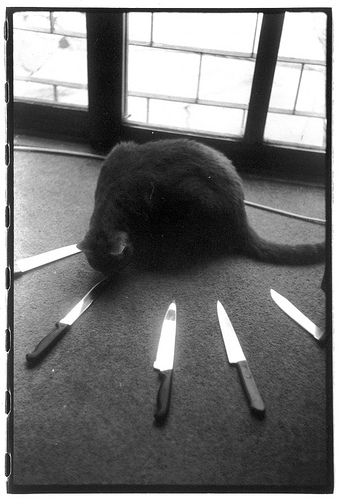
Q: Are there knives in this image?
A: Yes, there is a knife.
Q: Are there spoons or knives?
A: Yes, there is a knife.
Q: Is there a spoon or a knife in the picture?
A: Yes, there is a knife.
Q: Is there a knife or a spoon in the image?
A: Yes, there is a knife.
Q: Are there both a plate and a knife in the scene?
A: No, there is a knife but no plates.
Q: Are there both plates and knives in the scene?
A: No, there is a knife but no plates.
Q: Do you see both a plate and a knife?
A: No, there is a knife but no plates.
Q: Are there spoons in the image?
A: No, there are no spoons.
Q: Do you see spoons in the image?
A: No, there are no spoons.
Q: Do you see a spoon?
A: No, there are no spoons.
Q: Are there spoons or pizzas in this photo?
A: No, there are no spoons or pizzas.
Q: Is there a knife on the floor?
A: Yes, there is a knife on the floor.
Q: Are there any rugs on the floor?
A: No, there is a knife on the floor.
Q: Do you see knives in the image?
A: Yes, there is a knife.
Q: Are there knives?
A: Yes, there is a knife.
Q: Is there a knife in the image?
A: Yes, there is a knife.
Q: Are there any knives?
A: Yes, there is a knife.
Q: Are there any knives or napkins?
A: Yes, there is a knife.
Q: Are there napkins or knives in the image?
A: Yes, there is a knife.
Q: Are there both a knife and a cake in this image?
A: No, there is a knife but no cakes.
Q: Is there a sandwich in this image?
A: No, there are no sandwiches.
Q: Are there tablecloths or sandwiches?
A: No, there are no sandwiches or tablecloths.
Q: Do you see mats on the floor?
A: No, there is a knife on the floor.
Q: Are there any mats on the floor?
A: No, there is a knife on the floor.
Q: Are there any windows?
A: Yes, there is a window.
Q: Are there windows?
A: Yes, there is a window.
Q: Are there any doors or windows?
A: Yes, there is a window.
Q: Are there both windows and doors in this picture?
A: No, there is a window but no doors.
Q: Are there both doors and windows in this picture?
A: No, there is a window but no doors.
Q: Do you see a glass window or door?
A: Yes, there is a glass window.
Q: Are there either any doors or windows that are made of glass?
A: Yes, the window is made of glass.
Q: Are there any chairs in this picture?
A: No, there are no chairs.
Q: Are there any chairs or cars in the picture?
A: No, there are no chairs or cars.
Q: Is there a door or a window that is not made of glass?
A: No, there is a window but it is made of glass.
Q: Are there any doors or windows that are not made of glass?
A: No, there is a window but it is made of glass.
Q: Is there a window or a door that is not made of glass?
A: No, there is a window but it is made of glass.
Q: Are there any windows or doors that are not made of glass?
A: No, there is a window but it is made of glass.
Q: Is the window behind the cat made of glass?
A: Yes, the window is made of glass.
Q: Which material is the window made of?
A: The window is made of glass.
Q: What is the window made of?
A: The window is made of glass.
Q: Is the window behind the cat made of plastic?
A: No, the window is made of glass.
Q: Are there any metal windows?
A: No, there is a window but it is made of glass.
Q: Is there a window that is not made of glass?
A: No, there is a window but it is made of glass.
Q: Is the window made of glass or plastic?
A: The window is made of glass.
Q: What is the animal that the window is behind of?
A: The animal is a cat.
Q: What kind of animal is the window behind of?
A: The window is behind the cat.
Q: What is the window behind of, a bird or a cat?
A: The window is behind a cat.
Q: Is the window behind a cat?
A: Yes, the window is behind a cat.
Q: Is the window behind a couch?
A: No, the window is behind a cat.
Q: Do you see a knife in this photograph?
A: Yes, there is a knife.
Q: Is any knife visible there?
A: Yes, there is a knife.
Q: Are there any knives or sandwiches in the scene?
A: Yes, there is a knife.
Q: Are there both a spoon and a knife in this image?
A: No, there is a knife but no spoons.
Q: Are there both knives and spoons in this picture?
A: No, there is a knife but no spoons.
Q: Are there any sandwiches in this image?
A: No, there are no sandwiches.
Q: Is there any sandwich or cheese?
A: No, there are no sandwiches or cheese.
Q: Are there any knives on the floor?
A: Yes, there is a knife on the floor.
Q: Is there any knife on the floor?
A: Yes, there is a knife on the floor.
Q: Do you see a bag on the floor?
A: No, there is a knife on the floor.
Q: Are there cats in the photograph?
A: Yes, there is a cat.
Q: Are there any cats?
A: Yes, there is a cat.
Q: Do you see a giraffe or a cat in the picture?
A: Yes, there is a cat.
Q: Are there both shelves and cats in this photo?
A: No, there is a cat but no shelves.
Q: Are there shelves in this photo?
A: No, there are no shelves.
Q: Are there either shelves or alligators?
A: No, there are no shelves or alligators.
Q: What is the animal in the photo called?
A: The animal is a cat.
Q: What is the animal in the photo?
A: The animal is a cat.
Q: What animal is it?
A: The animal is a cat.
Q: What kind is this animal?
A: That is a cat.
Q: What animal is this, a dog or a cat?
A: That is a cat.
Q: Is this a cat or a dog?
A: This is a cat.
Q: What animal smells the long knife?
A: The cat smells the knife.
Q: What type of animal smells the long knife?
A: The animal is a cat.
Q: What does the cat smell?
A: The cat smells the knife.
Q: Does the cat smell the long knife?
A: Yes, the cat smells the knife.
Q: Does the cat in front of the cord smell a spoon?
A: No, the cat smells the knife.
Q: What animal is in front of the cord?
A: The cat is in front of the cord.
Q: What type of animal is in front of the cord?
A: The animal is a cat.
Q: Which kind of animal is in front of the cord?
A: The animal is a cat.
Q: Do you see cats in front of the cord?
A: Yes, there is a cat in front of the cord.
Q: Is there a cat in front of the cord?
A: Yes, there is a cat in front of the cord.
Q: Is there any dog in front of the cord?
A: No, there is a cat in front of the cord.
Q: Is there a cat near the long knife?
A: Yes, there is a cat near the knife.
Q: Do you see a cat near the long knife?
A: Yes, there is a cat near the knife.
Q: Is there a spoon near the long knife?
A: No, there is a cat near the knife.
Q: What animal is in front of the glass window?
A: The cat is in front of the window.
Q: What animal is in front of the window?
A: The cat is in front of the window.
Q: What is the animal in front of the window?
A: The animal is a cat.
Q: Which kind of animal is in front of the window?
A: The animal is a cat.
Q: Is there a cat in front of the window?
A: Yes, there is a cat in front of the window.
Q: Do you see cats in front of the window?
A: Yes, there is a cat in front of the window.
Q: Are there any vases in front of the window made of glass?
A: No, there is a cat in front of the window.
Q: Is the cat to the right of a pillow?
A: No, the cat is to the right of a knife.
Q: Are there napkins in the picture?
A: No, there are no napkins.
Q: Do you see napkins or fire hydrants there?
A: No, there are no napkins or fire hydrants.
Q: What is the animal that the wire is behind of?
A: The animal is a cat.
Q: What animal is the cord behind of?
A: The wire is behind the cat.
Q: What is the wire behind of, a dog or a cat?
A: The wire is behind a cat.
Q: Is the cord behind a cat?
A: Yes, the cord is behind a cat.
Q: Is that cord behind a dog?
A: No, the cord is behind a cat.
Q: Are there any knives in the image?
A: Yes, there is a knife.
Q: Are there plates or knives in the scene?
A: Yes, there is a knife.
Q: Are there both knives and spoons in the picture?
A: No, there is a knife but no spoons.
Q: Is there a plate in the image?
A: No, there are no plates.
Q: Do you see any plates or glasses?
A: No, there are no plates or glasses.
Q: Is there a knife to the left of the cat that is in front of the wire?
A: Yes, there is a knife to the left of the cat.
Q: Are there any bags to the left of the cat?
A: No, there is a knife to the left of the cat.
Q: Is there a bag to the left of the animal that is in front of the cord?
A: No, there is a knife to the left of the cat.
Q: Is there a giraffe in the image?
A: No, there are no giraffes.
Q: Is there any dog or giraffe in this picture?
A: No, there are no giraffes or dogs.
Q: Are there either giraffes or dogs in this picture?
A: No, there are no giraffes or dogs.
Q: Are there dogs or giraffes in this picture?
A: No, there are no giraffes or dogs.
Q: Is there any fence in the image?
A: No, there are no fences.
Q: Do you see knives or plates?
A: Yes, there is a knife.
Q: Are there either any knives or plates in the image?
A: Yes, there is a knife.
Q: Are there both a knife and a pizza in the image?
A: No, there is a knife but no pizzas.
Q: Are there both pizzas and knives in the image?
A: No, there is a knife but no pizzas.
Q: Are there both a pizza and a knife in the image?
A: No, there is a knife but no pizzas.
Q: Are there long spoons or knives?
A: Yes, there is a long knife.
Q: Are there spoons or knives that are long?
A: Yes, the knife is long.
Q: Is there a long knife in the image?
A: Yes, there is a long knife.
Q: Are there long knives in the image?
A: Yes, there is a long knife.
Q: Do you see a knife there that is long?
A: Yes, there is a knife that is long.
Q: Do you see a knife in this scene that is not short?
A: Yes, there is a long knife.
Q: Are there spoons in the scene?
A: No, there are no spoons.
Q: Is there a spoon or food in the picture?
A: No, there are no spoons or food.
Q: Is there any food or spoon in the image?
A: No, there are no spoons or food.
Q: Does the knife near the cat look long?
A: Yes, the knife is long.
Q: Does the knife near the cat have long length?
A: Yes, the knife is long.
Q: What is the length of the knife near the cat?
A: The knife is long.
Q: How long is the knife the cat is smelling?
A: The knife is long.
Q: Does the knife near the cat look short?
A: No, the knife is long.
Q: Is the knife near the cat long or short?
A: The knife is long.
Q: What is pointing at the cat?
A: The knife is pointing at the cat.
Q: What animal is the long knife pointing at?
A: The knife is pointing at the cat.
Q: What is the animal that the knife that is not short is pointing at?
A: The animal is a cat.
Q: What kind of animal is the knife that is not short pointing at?
A: The knife is pointing at the cat.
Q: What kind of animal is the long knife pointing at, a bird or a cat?
A: The knife is pointing at a cat.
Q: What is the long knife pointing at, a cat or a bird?
A: The knife is pointing at a cat.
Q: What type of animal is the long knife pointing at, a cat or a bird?
A: The knife is pointing at a cat.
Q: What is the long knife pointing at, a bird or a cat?
A: The knife is pointing at a cat.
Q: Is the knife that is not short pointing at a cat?
A: Yes, the knife is pointing at a cat.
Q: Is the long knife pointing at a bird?
A: No, the knife is pointing at a cat.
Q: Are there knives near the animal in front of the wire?
A: Yes, there is a knife near the cat.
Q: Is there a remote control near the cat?
A: No, there is a knife near the cat.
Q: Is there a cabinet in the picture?
A: No, there are no cabinets.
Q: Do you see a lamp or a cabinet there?
A: No, there are no cabinets or lamps.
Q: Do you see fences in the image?
A: No, there are no fences.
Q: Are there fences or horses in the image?
A: No, there are no fences or horses.